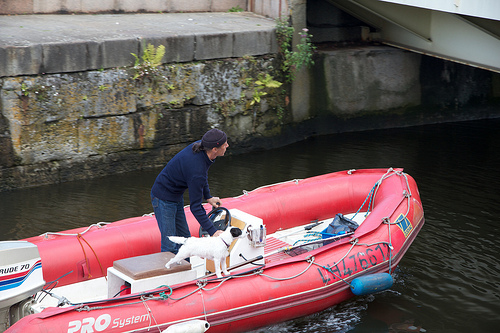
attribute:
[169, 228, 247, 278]
dog — small, white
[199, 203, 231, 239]
wheel — black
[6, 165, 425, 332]
boat — red, floating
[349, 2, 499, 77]
bridge — metal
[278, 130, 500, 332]
water — murky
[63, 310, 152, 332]
writing — white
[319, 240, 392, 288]
number — black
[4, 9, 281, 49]
platform — gray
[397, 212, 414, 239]
sign — small, square